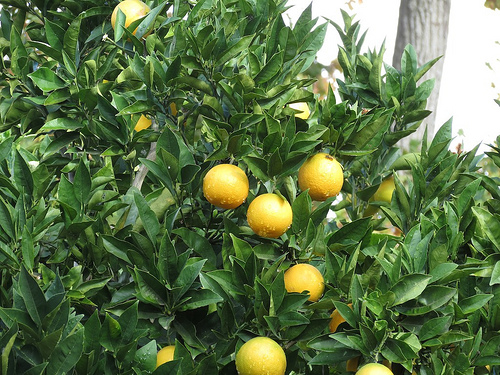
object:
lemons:
[111, 0, 155, 42]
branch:
[13, 49, 189, 336]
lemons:
[169, 102, 178, 117]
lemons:
[328, 303, 353, 332]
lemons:
[355, 363, 394, 375]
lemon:
[298, 152, 344, 201]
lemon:
[247, 193, 293, 238]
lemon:
[202, 163, 249, 209]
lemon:
[284, 263, 325, 303]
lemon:
[235, 337, 288, 375]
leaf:
[172, 258, 209, 303]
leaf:
[229, 232, 253, 263]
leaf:
[133, 190, 161, 259]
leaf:
[326, 247, 342, 288]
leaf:
[257, 110, 281, 143]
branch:
[395, 202, 491, 360]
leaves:
[75, 275, 113, 297]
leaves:
[458, 294, 495, 315]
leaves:
[34, 117, 85, 134]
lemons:
[346, 193, 380, 217]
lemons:
[346, 354, 392, 372]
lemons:
[374, 176, 397, 204]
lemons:
[130, 113, 152, 132]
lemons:
[156, 345, 176, 368]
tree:
[0, 132, 151, 375]